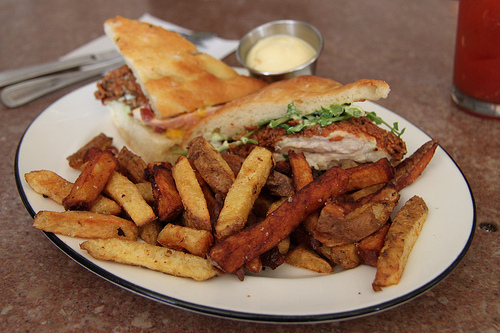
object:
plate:
[11, 81, 476, 326]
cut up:
[169, 135, 442, 293]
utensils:
[0, 52, 121, 109]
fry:
[369, 194, 429, 293]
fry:
[388, 136, 441, 193]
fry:
[171, 154, 216, 230]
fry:
[78, 232, 220, 282]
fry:
[31, 208, 148, 240]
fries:
[24, 127, 444, 298]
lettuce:
[268, 100, 406, 139]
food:
[26, 14, 444, 293]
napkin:
[57, 13, 240, 61]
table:
[0, 5, 499, 329]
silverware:
[0, 29, 219, 109]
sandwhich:
[96, 16, 392, 147]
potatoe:
[206, 146, 349, 271]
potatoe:
[370, 194, 429, 292]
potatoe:
[78, 235, 220, 282]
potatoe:
[171, 155, 213, 232]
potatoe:
[30, 207, 136, 241]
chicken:
[240, 116, 406, 171]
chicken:
[93, 64, 145, 112]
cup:
[234, 20, 325, 83]